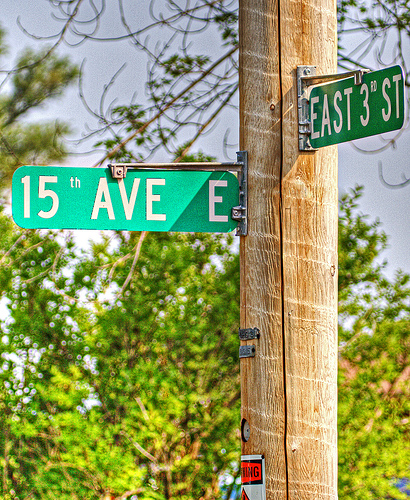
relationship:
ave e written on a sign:
[89, 173, 232, 225] [10, 164, 242, 235]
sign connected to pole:
[237, 452, 268, 499] [237, 2, 339, 499]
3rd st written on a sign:
[357, 75, 404, 127] [305, 64, 403, 150]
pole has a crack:
[237, 2, 339, 499] [272, 2, 295, 499]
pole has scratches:
[237, 2, 339, 499] [247, 12, 325, 321]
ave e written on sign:
[89, 173, 232, 225] [10, 164, 242, 235]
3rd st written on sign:
[357, 75, 404, 127] [305, 64, 403, 150]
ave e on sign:
[89, 173, 232, 225] [10, 164, 242, 235]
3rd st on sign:
[357, 75, 404, 127] [305, 64, 403, 150]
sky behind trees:
[0, 1, 407, 377] [0, 27, 409, 500]